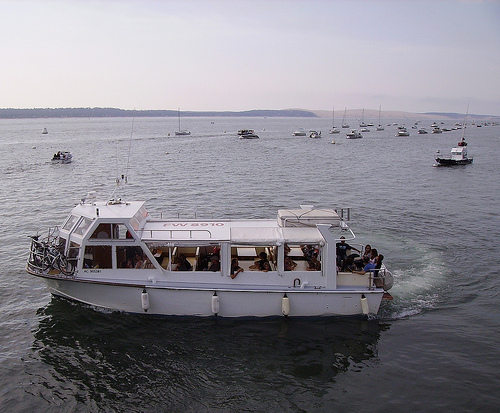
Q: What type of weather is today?
A: It is clear.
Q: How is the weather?
A: It is clear.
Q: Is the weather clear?
A: Yes, it is clear.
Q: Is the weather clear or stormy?
A: It is clear.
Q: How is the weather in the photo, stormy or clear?
A: It is clear.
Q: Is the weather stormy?
A: No, it is clear.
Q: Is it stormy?
A: No, it is clear.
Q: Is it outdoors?
A: Yes, it is outdoors.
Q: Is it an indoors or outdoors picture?
A: It is outdoors.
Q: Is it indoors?
A: No, it is outdoors.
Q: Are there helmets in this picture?
A: No, there are no helmets.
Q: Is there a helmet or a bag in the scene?
A: No, there are no helmets or bags.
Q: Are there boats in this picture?
A: Yes, there is a boat.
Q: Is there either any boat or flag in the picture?
A: Yes, there is a boat.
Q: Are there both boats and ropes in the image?
A: No, there is a boat but no ropes.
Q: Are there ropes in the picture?
A: No, there are no ropes.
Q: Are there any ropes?
A: No, there are no ropes.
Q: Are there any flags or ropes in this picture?
A: No, there are no ropes or flags.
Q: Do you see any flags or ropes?
A: No, there are no ropes or flags.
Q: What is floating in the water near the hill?
A: The boat is floating in the water.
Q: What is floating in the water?
A: The boat is floating in the water.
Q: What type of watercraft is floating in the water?
A: The watercraft is a boat.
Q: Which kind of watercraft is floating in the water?
A: The watercraft is a boat.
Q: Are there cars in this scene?
A: No, there are no cars.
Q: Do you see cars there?
A: No, there are no cars.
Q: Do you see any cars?
A: No, there are no cars.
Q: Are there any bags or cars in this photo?
A: No, there are no cars or bags.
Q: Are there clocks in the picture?
A: No, there are no clocks.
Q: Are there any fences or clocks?
A: No, there are no clocks or fences.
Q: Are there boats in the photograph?
A: Yes, there is a boat.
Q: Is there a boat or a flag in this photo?
A: Yes, there is a boat.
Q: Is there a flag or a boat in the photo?
A: Yes, there is a boat.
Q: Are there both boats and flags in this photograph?
A: No, there is a boat but no flags.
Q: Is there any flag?
A: No, there are no flags.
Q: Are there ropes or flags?
A: No, there are no flags or ropes.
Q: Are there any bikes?
A: Yes, there are bikes.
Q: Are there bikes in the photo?
A: Yes, there are bikes.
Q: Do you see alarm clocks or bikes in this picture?
A: Yes, there are bikes.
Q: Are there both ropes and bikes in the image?
A: No, there are bikes but no ropes.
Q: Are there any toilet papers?
A: No, there are no toilet papers.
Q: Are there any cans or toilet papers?
A: No, there are no toilet papers or cans.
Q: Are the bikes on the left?
A: Yes, the bikes are on the left of the image.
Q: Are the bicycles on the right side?
A: No, the bicycles are on the left of the image.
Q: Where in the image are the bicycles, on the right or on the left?
A: The bicycles are on the left of the image.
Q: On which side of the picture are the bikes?
A: The bikes are on the left of the image.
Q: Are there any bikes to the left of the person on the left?
A: Yes, there are bikes to the left of the person.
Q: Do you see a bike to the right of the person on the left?
A: No, the bikes are to the left of the person.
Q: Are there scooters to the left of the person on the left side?
A: No, there are bikes to the left of the person.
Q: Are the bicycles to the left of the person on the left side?
A: Yes, the bicycles are to the left of the person.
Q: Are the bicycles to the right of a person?
A: No, the bicycles are to the left of a person.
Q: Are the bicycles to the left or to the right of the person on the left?
A: The bicycles are to the left of the person.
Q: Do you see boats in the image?
A: Yes, there is a boat.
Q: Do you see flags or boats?
A: Yes, there is a boat.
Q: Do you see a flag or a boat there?
A: Yes, there is a boat.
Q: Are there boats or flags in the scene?
A: Yes, there is a boat.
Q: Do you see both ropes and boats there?
A: No, there is a boat but no ropes.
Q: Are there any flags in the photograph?
A: No, there are no flags.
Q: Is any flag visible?
A: No, there are no flags.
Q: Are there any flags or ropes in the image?
A: No, there are no flags or ropes.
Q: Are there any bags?
A: No, there are no bags.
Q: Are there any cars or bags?
A: No, there are no bags or cars.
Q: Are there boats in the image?
A: Yes, there is a boat.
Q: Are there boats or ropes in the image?
A: Yes, there is a boat.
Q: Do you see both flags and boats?
A: No, there is a boat but no flags.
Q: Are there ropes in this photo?
A: No, there are no ropes.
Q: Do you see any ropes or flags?
A: No, there are no ropes or flags.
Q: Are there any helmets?
A: No, there are no helmets.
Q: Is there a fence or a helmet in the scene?
A: No, there are no helmets or fences.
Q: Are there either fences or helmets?
A: No, there are no helmets or fences.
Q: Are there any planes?
A: No, there are no planes.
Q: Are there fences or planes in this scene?
A: No, there are no planes or fences.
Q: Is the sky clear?
A: Yes, the sky is clear.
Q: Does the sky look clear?
A: Yes, the sky is clear.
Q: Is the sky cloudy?
A: No, the sky is clear.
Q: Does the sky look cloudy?
A: No, the sky is clear.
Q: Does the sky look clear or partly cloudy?
A: The sky is clear.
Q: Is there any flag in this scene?
A: No, there are no flags.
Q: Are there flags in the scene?
A: No, there are no flags.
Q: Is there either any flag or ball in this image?
A: No, there are no flags or balls.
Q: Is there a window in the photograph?
A: Yes, there is a window.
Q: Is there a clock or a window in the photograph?
A: Yes, there is a window.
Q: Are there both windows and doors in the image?
A: No, there is a window but no doors.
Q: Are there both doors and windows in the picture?
A: No, there is a window but no doors.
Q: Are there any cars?
A: No, there are no cars.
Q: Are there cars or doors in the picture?
A: No, there are no cars or doors.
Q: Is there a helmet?
A: No, there are no helmets.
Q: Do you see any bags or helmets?
A: No, there are no helmets or bags.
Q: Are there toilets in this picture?
A: No, there are no toilets.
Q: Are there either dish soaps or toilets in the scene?
A: No, there are no toilets or dish soaps.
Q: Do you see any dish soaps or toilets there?
A: No, there are no toilets or dish soaps.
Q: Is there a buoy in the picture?
A: Yes, there is a buoy.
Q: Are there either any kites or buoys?
A: Yes, there is a buoy.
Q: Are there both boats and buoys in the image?
A: Yes, there are both a buoy and a boat.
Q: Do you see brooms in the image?
A: No, there are no brooms.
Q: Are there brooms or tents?
A: No, there are no brooms or tents.